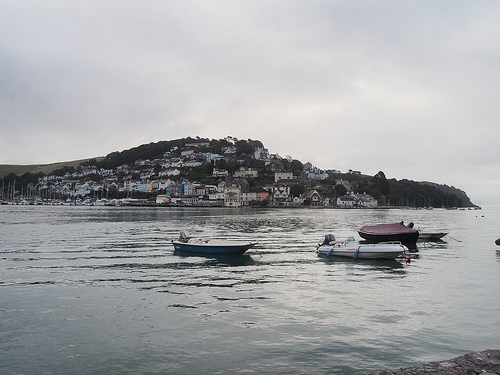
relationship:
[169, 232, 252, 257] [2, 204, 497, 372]
boat on water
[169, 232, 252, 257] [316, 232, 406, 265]
boat next to boat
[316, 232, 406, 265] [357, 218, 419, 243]
boat next to boat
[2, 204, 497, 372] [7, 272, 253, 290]
water has ripple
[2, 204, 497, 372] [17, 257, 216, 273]
water has ripple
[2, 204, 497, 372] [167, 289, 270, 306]
water has ripple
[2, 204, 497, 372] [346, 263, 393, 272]
water has ripple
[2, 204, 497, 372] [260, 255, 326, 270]
water has ripple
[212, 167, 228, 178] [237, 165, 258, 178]
house next to house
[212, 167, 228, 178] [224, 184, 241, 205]
house next to house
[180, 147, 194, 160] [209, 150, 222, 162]
house next to house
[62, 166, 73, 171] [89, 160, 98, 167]
tree next to tree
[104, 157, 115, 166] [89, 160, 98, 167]
tree next to tree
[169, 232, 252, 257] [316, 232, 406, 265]
boat near boat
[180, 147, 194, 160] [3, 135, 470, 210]
house on hill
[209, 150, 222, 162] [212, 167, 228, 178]
house next to house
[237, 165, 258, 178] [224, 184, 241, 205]
house next to house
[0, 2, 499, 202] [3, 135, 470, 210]
sky above hill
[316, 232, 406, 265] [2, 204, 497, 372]
boat on water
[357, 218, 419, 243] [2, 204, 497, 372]
boat on water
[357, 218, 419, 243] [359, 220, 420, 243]
boat has cover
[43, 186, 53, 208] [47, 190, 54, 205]
sailboat next to sailboat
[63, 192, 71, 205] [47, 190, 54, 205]
sailboat next to sailboat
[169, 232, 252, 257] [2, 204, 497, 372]
boat floating in water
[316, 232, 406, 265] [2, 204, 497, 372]
boat floating in water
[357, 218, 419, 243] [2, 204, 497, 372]
boat floating in water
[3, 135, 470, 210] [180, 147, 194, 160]
hill has house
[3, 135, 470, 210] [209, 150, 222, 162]
hill has house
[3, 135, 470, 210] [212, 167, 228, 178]
hill has house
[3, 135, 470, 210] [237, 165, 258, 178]
hill has house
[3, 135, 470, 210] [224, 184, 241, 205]
hill has house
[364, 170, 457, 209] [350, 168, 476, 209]
forest on end of hill